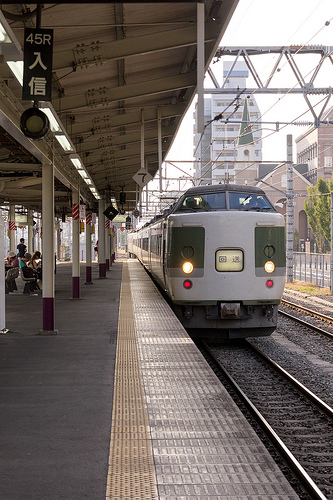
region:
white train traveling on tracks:
[129, 187, 286, 340]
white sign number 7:
[133, 167, 151, 186]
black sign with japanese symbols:
[22, 26, 52, 98]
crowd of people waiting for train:
[4, 239, 45, 292]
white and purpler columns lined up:
[40, 155, 117, 326]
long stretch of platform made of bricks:
[107, 257, 299, 498]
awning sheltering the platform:
[1, 15, 229, 213]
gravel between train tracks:
[248, 297, 330, 496]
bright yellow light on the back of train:
[182, 260, 193, 274]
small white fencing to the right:
[293, 251, 329, 283]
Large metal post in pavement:
[32, 163, 67, 347]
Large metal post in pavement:
[65, 184, 82, 301]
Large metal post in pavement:
[81, 202, 96, 293]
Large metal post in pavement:
[94, 200, 106, 285]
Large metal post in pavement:
[105, 219, 113, 278]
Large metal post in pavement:
[35, 163, 132, 341]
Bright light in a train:
[169, 260, 204, 283]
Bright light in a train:
[262, 258, 281, 278]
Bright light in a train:
[257, 278, 283, 295]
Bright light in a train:
[180, 274, 199, 298]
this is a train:
[117, 172, 293, 358]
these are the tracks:
[149, 255, 332, 497]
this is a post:
[27, 160, 68, 337]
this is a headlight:
[180, 255, 201, 281]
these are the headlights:
[173, 255, 278, 286]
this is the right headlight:
[175, 253, 197, 274]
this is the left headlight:
[261, 258, 285, 280]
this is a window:
[174, 184, 274, 215]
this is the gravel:
[281, 335, 331, 403]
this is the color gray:
[209, 215, 232, 247]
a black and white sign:
[18, 21, 65, 124]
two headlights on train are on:
[179, 253, 291, 285]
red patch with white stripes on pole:
[67, 195, 87, 224]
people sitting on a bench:
[15, 243, 54, 288]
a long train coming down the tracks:
[121, 177, 286, 337]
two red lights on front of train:
[183, 273, 300, 295]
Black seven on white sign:
[122, 159, 161, 190]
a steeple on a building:
[228, 91, 271, 172]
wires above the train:
[133, 69, 314, 209]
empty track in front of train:
[212, 345, 331, 474]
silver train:
[109, 173, 307, 341]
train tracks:
[182, 324, 331, 481]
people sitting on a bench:
[16, 247, 48, 299]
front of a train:
[159, 187, 298, 315]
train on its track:
[97, 174, 324, 386]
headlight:
[180, 258, 194, 272]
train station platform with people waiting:
[3, 198, 228, 497]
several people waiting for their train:
[1, 229, 59, 306]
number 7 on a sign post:
[129, 164, 152, 187]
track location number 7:
[127, 162, 154, 191]